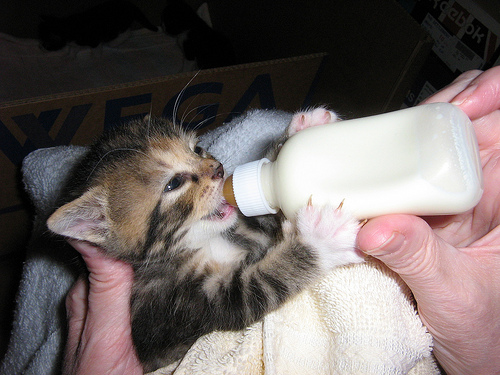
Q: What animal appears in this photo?
A: A kitten.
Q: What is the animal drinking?
A: Milk.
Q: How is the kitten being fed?
A: Through a bottle.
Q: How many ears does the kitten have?
A: 2.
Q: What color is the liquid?
A: White.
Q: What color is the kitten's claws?
A: Pink.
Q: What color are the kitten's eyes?
A: Black.